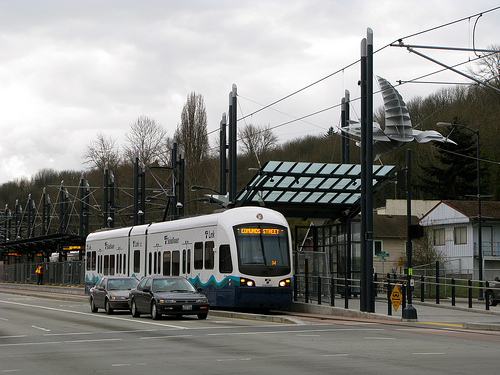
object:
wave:
[186, 273, 240, 290]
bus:
[83, 205, 296, 313]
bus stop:
[233, 161, 399, 318]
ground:
[0, 284, 500, 375]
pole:
[356, 28, 377, 315]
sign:
[236, 227, 284, 236]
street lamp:
[336, 74, 458, 312]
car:
[128, 276, 210, 321]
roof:
[236, 160, 398, 206]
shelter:
[236, 158, 399, 301]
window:
[276, 160, 293, 173]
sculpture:
[339, 78, 457, 162]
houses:
[318, 197, 498, 309]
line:
[0, 293, 188, 347]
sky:
[0, 0, 500, 186]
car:
[89, 277, 142, 315]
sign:
[390, 283, 404, 312]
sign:
[376, 250, 390, 262]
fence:
[295, 220, 354, 309]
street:
[0, 290, 499, 374]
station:
[0, 78, 498, 311]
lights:
[239, 278, 291, 287]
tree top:
[171, 93, 210, 197]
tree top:
[122, 118, 167, 166]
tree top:
[82, 131, 124, 174]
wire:
[192, 127, 222, 142]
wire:
[192, 145, 223, 155]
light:
[190, 185, 198, 192]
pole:
[191, 186, 222, 194]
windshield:
[237, 224, 290, 266]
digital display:
[240, 228, 279, 235]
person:
[35, 263, 44, 285]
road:
[1, 282, 497, 375]